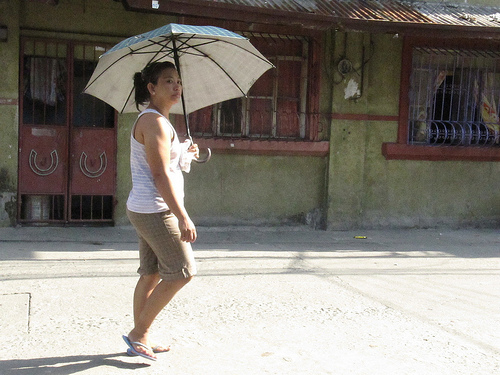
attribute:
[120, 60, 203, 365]
woman — walking, in city, in sunshine, going to see friend, in asian country, enjoying day, grocery shopping, looking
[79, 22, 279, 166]
umbrella — open, striped, white, blue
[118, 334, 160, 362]
flip flop — pastel, light blue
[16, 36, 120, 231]
door — metal, red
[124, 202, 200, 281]
pants — tan, beige, plaid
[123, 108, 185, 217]
tank top — white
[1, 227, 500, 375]
sidewalk — paved, ragged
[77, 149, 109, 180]
horse shoe — white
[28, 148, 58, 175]
horse shoe — white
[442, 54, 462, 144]
bar — metal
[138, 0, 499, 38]
roof — rusted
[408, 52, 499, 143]
curtain — faded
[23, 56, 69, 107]
curtain — red